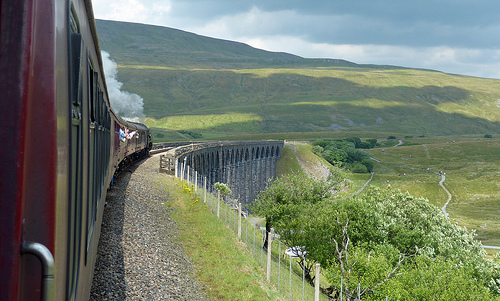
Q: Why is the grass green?
A: Photosynthesis.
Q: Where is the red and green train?
A: On the railroad tracks.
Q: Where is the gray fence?
A: On the hill.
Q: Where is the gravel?
A: Alongside the train tracks.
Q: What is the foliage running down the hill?
A: Trees and brush.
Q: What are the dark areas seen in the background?
A: Grassy hillsides.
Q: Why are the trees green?
A: Natural chlorophyll.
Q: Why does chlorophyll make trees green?
A: Nature.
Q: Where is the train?
A: On the tracks.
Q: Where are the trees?
A: On the hillside.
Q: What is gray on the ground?
A: Gravel.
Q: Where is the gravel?
A: Next to the train.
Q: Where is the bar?
A: On the train.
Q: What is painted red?
A: The train.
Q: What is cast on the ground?
A: Shadows.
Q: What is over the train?
A: Smoke.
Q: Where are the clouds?
A: In the sky.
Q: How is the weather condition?
A: Cloudy and fair.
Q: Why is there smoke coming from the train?
A: Steam coming from the engine.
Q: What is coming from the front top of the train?
A: Smoke.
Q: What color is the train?
A: Red.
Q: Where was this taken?
A: The Countryside.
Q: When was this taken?
A: Daytime.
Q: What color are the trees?
A: Green.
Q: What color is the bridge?
A: Gray.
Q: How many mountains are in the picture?
A: 1.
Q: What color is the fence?
A: Grey.